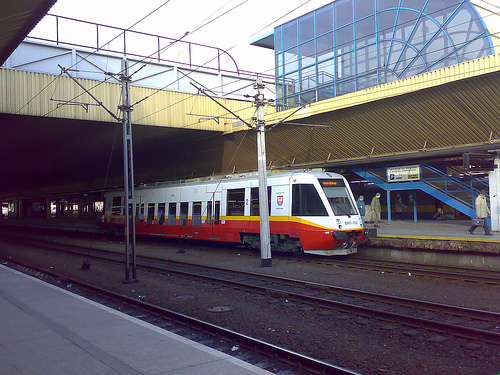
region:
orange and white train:
[134, 165, 362, 264]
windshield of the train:
[318, 185, 356, 215]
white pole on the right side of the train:
[255, 90, 272, 262]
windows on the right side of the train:
[147, 185, 273, 227]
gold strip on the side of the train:
[139, 213, 363, 232]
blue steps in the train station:
[355, 165, 476, 236]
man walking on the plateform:
[367, 189, 383, 226]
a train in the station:
[96, 166, 366, 258]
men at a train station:
[351, 188, 386, 227]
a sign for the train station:
[381, 162, 424, 184]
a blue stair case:
[356, 154, 491, 229]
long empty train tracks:
[3, 222, 495, 374]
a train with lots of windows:
[98, 169, 366, 261]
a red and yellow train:
[97, 169, 367, 260]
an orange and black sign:
[315, 175, 347, 190]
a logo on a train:
[273, 190, 289, 213]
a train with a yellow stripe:
[97, 169, 366, 260]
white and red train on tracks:
[100, 168, 366, 256]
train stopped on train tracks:
[96, 165, 365, 269]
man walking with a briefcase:
[466, 187, 494, 235]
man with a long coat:
[367, 191, 383, 230]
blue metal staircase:
[352, 156, 492, 226]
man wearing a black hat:
[463, 184, 493, 237]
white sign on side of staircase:
[382, 162, 423, 184]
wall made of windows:
[273, 0, 498, 111]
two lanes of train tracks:
[0, 214, 498, 359]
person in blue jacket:
[353, 193, 365, 224]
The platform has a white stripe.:
[81, 292, 162, 344]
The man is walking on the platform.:
[468, 187, 490, 241]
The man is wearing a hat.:
[473, 189, 489, 199]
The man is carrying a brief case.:
[467, 212, 487, 230]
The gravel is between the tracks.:
[306, 322, 374, 356]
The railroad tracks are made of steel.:
[329, 281, 444, 336]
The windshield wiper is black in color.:
[328, 194, 353, 220]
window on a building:
[278, 20, 298, 50]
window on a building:
[298, 12, 313, 41]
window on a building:
[314, 5, 334, 33]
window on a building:
[333, 1, 351, 27]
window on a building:
[375, 10, 393, 39]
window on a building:
[351, 17, 375, 42]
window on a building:
[313, 29, 333, 60]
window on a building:
[283, 45, 300, 71]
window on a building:
[281, 70, 300, 96]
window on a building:
[336, 50, 354, 77]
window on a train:
[323, 185, 357, 215]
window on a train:
[291, 182, 328, 218]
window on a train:
[249, 185, 271, 214]